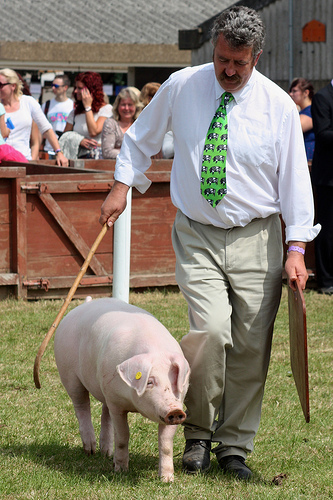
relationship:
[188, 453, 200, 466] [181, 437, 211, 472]
dirt on shoe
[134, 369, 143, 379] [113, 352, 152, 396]
tag on ear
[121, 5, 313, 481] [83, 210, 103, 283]
man holding stick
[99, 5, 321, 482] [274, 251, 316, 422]
man holding brown board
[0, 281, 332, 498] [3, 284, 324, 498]
grass on ground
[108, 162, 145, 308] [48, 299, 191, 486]
pole behind pig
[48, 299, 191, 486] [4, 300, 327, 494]
pig on grass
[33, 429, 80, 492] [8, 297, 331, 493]
grass covers ground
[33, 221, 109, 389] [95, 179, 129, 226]
stick in hand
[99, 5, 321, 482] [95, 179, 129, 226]
man has hand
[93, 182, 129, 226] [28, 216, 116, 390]
hand holds stick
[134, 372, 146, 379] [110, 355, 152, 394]
tag in ear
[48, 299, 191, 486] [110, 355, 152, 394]
pig has ear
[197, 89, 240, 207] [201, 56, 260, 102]
green tie around neck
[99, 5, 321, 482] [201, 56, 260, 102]
man has neck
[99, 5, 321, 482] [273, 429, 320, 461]
man walks on grass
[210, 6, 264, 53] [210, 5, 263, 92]
hair on head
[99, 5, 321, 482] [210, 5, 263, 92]
man has head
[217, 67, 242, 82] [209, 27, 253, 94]
mustache on face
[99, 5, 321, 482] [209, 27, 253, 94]
man has face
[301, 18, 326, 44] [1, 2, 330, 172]
object on building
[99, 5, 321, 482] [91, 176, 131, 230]
man had hand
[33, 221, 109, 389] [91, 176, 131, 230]
stick in hand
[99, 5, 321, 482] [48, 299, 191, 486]
man stands beside pig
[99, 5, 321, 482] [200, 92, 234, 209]
man wears green tie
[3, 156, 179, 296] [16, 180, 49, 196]
fence has bolt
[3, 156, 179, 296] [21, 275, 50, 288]
fence has bolt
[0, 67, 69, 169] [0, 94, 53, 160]
person has shirt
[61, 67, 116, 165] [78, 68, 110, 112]
lady has hair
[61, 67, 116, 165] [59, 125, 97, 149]
lady has arm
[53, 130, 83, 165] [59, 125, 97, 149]
sweater over arm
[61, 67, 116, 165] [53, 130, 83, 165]
lady holds sweater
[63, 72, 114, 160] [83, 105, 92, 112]
lady wears watch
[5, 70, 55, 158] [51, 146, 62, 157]
person wears watch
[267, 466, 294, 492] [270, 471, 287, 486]
lump on lump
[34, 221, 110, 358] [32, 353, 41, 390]
stick has crook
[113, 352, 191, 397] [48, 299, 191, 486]
ears on pig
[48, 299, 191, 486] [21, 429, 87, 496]
pig in grass.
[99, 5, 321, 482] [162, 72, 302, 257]
man with shirt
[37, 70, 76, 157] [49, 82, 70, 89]
man has shades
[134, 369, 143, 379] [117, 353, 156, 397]
tag on ear